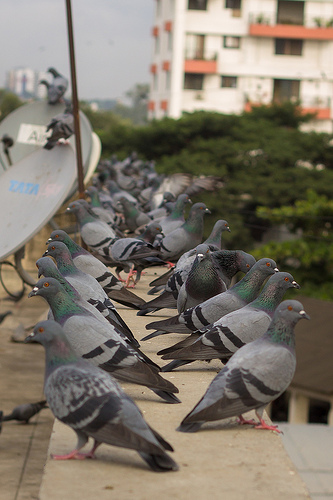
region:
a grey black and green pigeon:
[23, 321, 181, 473]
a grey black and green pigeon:
[27, 277, 178, 402]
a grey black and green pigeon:
[43, 238, 116, 308]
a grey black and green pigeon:
[100, 232, 171, 289]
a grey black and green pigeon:
[177, 297, 310, 432]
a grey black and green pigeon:
[158, 271, 301, 372]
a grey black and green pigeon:
[141, 256, 279, 344]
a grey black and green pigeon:
[174, 242, 228, 312]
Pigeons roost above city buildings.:
[39, 141, 307, 474]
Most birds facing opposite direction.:
[24, 183, 299, 442]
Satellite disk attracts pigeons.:
[1, 66, 98, 249]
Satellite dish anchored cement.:
[0, 163, 38, 314]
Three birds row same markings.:
[172, 254, 306, 440]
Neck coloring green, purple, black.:
[49, 279, 91, 328]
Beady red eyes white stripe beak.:
[256, 255, 305, 299]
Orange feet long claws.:
[223, 402, 295, 451]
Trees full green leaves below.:
[120, 112, 332, 209]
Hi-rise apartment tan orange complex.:
[135, 2, 329, 126]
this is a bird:
[21, 316, 180, 484]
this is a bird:
[20, 279, 177, 406]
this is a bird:
[31, 253, 152, 371]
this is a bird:
[50, 220, 155, 315]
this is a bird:
[69, 201, 156, 277]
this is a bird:
[84, 184, 148, 233]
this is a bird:
[95, 177, 141, 207]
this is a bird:
[180, 296, 315, 441]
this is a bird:
[169, 272, 308, 348]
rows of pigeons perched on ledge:
[21, 125, 298, 462]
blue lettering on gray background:
[5, 174, 43, 195]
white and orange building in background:
[144, 3, 331, 123]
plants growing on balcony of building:
[249, 8, 331, 37]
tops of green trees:
[149, 88, 325, 245]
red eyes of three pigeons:
[264, 259, 294, 314]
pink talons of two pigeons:
[47, 418, 281, 470]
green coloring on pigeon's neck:
[52, 347, 77, 371]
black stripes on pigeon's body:
[61, 386, 120, 434]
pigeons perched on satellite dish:
[8, 61, 89, 158]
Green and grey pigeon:
[16, 318, 183, 478]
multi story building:
[152, 0, 329, 135]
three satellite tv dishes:
[0, 94, 108, 278]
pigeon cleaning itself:
[171, 243, 260, 314]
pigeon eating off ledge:
[92, 236, 179, 284]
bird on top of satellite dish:
[45, 105, 88, 153]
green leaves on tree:
[173, 118, 328, 204]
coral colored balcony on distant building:
[182, 52, 216, 72]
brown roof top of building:
[291, 294, 329, 388]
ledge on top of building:
[48, 464, 312, 498]